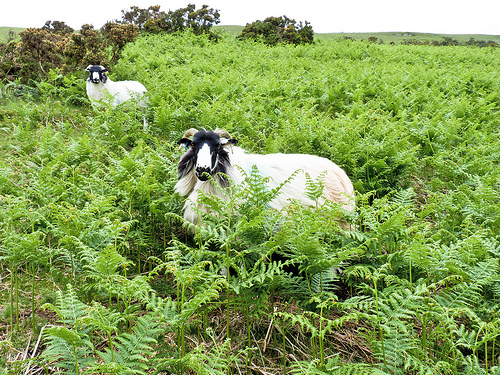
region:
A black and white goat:
[175, 118, 357, 225]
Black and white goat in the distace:
[81, 61, 147, 108]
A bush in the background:
[1, 18, 136, 70]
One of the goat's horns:
[179, 126, 200, 138]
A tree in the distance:
[239, 16, 319, 48]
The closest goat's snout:
[196, 155, 213, 179]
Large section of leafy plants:
[197, 31, 499, 129]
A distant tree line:
[350, 33, 499, 50]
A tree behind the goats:
[118, 7, 220, 38]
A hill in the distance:
[308, 28, 488, 40]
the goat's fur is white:
[216, 139, 316, 239]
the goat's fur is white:
[94, 69, 156, 129]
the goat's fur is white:
[252, 142, 350, 245]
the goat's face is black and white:
[162, 124, 244, 201]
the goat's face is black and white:
[76, 47, 134, 109]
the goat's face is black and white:
[78, 49, 110, 86]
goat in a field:
[155, 102, 395, 289]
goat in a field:
[79, 60, 151, 137]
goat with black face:
[173, 123, 369, 275]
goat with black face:
[79, 59, 164, 140]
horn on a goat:
[172, 120, 198, 151]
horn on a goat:
[210, 127, 242, 145]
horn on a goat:
[83, 61, 96, 76]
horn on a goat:
[100, 62, 112, 74]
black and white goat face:
[177, 129, 237, 185]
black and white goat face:
[83, 62, 108, 89]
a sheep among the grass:
[158, 112, 386, 251]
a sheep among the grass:
[64, 66, 143, 125]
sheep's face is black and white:
[151, 120, 290, 206]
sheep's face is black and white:
[68, 47, 163, 111]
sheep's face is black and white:
[173, 114, 240, 196]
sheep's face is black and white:
[77, 52, 127, 97]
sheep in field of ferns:
[163, 117, 365, 272]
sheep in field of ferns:
[89, 66, 149, 116]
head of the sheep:
[180, 128, 228, 180]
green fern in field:
[112, 319, 167, 359]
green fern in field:
[297, 318, 348, 344]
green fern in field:
[86, 249, 113, 275]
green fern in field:
[423, 241, 460, 273]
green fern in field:
[397, 185, 412, 217]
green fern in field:
[61, 175, 93, 207]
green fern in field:
[106, 164, 141, 197]